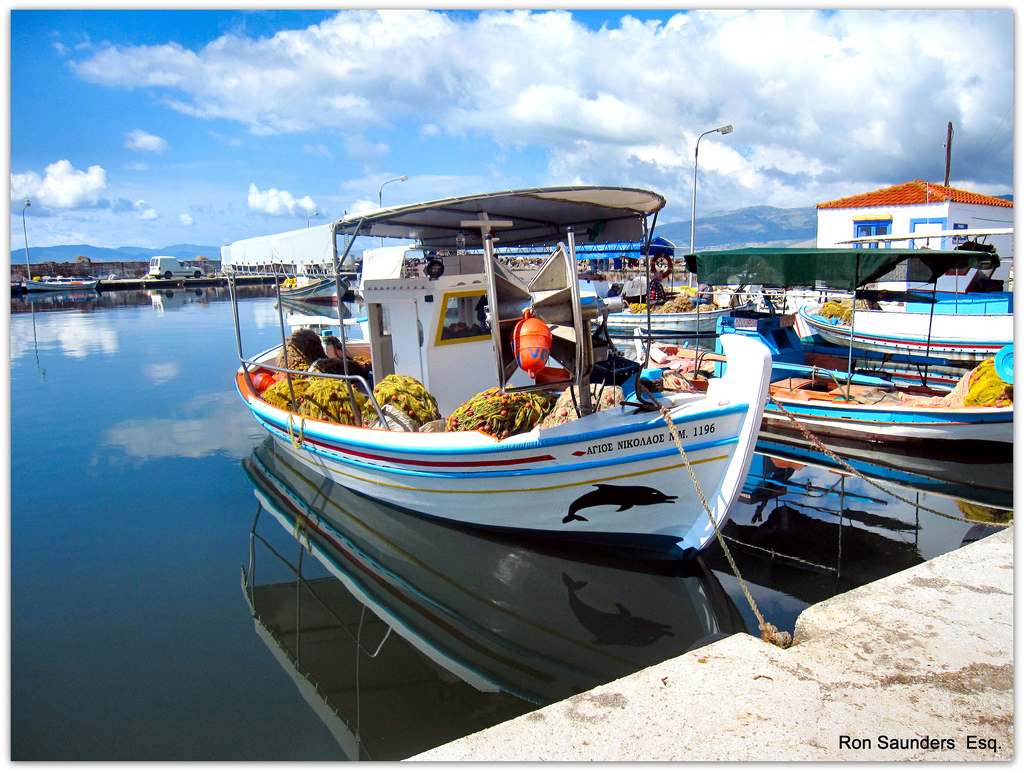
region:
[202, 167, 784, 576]
boat docked at pier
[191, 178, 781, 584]
boat docked is white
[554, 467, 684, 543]
dolphin picture on boat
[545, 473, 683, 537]
picture on boat is black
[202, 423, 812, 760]
reflection of boat in water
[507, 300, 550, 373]
buoy attached to boat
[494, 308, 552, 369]
buoy on boat is orange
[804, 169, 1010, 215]
roof of building is orange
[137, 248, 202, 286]
truck driving on road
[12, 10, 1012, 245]
clouds in daytime sky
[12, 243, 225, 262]
hay mountains on horizon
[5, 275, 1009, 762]
surface of calm water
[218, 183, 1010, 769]
fishing boat tied to dock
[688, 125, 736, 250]
light on curved pole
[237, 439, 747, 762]
reflection of boat on water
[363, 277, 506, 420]
wheelhouse of fishing boat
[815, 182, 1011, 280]
building with tiled roof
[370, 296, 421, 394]
open door of wheelhouse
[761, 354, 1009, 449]
a boat on the water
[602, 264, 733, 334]
a boat on the water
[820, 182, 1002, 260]
a house on a street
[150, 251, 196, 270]
a car in a parking lot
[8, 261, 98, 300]
a boat on the water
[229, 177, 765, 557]
boat in the calm water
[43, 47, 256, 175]
Large body of skies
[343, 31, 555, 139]
Large body of skies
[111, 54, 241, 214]
Large body of skies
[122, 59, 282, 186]
Large body of skies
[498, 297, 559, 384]
An orange floating thing on a boat.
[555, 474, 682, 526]
The symbole of a dophin on the side of a boat.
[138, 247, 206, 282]
A white truck in the back ground.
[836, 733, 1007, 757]
The name of the person who took the picture.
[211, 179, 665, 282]
A white awning on a boat.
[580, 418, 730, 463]
The name of the boat in black lettering.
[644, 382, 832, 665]
The rope holding the boat at the dock.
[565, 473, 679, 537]
black dolphin on white boat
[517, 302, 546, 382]
orange flotation device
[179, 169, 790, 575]
A boat on the water.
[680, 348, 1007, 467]
A boat on the water.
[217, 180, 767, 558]
the boat has a canopy over it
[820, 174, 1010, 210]
orange terracotta roof shingles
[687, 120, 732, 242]
streetlight on a pole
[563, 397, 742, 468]
blue stripes on a white surface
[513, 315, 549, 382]
the buoy is orange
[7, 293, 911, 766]
the water's surface is calm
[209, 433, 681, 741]
a boat's reflection on the water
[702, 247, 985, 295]
the canopy is green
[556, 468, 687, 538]
a picture of a dolphin on a boat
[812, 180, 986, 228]
a building with a red roof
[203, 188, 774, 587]
a boat in the water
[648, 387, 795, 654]
a rope attached to a boat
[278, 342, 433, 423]
several nets on a boat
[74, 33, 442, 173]
white clouds in the sky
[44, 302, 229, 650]
a body of calm water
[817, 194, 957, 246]
a white building with blue trim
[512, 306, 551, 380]
the buoy is orange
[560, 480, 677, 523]
the picture of the black dolphin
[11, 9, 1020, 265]
the white clouds in the blue sky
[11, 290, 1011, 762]
the water is dark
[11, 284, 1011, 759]
the reflection in the water